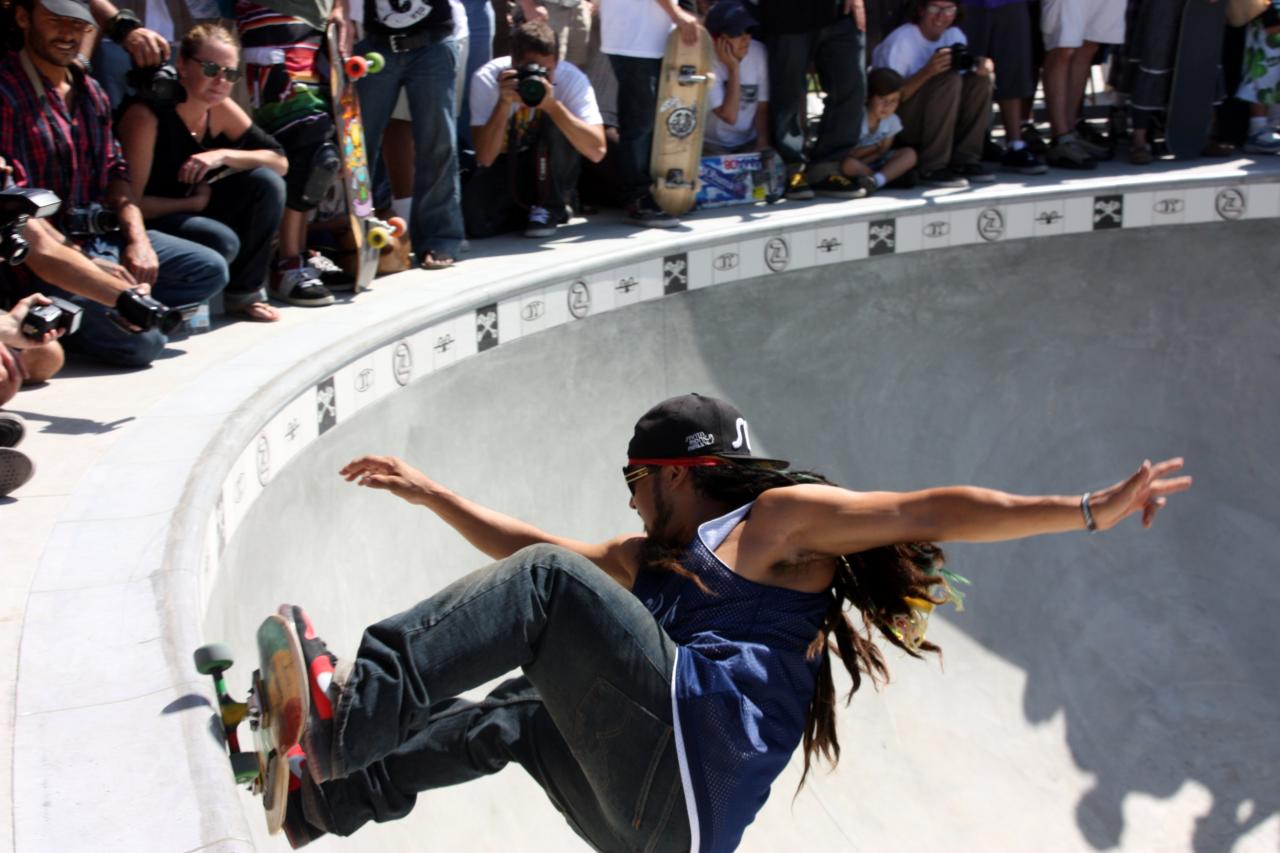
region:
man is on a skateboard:
[218, 383, 1227, 827]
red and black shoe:
[274, 597, 361, 768]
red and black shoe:
[286, 720, 339, 851]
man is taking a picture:
[461, 12, 607, 220]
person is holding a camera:
[6, 171, 188, 342]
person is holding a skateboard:
[597, 5, 728, 244]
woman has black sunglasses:
[187, 54, 249, 90]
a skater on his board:
[195, 373, 1213, 828]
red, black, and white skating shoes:
[279, 600, 357, 832]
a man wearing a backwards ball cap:
[612, 401, 789, 529]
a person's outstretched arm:
[773, 463, 1093, 552]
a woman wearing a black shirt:
[142, 28, 286, 190]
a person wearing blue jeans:
[330, 540, 692, 841]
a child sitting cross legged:
[830, 68, 925, 192]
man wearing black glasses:
[609, 452, 652, 483]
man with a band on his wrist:
[1068, 487, 1100, 540]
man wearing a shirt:
[613, 492, 843, 824]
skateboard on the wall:
[178, 598, 327, 791]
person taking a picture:
[509, 46, 545, 102]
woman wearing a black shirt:
[139, 86, 268, 175]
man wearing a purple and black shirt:
[8, 61, 132, 240]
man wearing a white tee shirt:
[884, 9, 969, 63]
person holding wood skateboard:
[595, 7, 724, 226]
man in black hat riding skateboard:
[199, 354, 1213, 847]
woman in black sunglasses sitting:
[107, 25, 299, 339]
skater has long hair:
[684, 437, 979, 814]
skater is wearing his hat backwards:
[622, 394, 797, 475]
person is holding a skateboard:
[652, 18, 717, 221]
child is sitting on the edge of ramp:
[856, 55, 914, 205]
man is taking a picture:
[475, 29, 596, 112]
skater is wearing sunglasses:
[605, 439, 663, 500]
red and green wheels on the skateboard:
[337, 44, 398, 83]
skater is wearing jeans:
[305, 534, 698, 849]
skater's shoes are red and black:
[273, 601, 332, 849]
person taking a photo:
[468, 28, 606, 238]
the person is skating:
[139, 357, 1237, 850]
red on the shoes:
[264, 587, 384, 850]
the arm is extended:
[706, 381, 1227, 646]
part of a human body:
[264, 589, 359, 791]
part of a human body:
[327, 530, 526, 727]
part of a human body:
[744, 444, 1080, 564]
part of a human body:
[424, 466, 654, 597]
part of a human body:
[612, 380, 785, 555]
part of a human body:
[11, 218, 184, 353]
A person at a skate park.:
[884, 36, 1024, 202]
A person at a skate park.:
[838, 51, 956, 213]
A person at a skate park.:
[736, 5, 898, 224]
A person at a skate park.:
[697, 1, 810, 193]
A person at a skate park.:
[618, 0, 714, 223]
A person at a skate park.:
[494, 27, 640, 239]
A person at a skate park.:
[370, 0, 508, 285]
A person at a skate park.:
[145, 20, 309, 314]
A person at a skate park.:
[224, 310, 1198, 814]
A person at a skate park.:
[33, 1, 239, 359]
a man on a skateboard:
[303, 394, 1191, 849]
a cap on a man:
[625, 392, 789, 466]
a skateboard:
[192, 610, 309, 825]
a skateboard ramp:
[174, 164, 1276, 849]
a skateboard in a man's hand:
[324, 28, 406, 296]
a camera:
[113, 279, 180, 339]